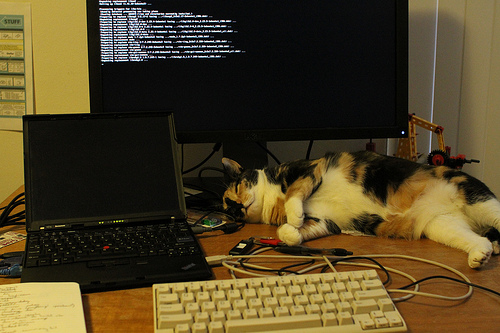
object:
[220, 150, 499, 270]
cat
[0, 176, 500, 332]
desk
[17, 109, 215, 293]
laptop computer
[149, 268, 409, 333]
computer keyboard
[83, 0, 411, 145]
computer monitor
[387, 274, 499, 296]
cables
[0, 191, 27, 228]
cords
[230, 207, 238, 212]
eye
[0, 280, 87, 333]
note book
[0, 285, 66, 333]
writing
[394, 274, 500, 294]
usb cable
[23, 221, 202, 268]
keyboard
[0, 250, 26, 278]
dvd disc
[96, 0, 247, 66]
scripts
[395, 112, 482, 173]
construction vehicle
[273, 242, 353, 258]
pen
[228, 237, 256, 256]
thumb drive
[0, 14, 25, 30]
paper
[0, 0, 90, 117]
wall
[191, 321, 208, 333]
key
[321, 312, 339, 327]
key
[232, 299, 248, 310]
key